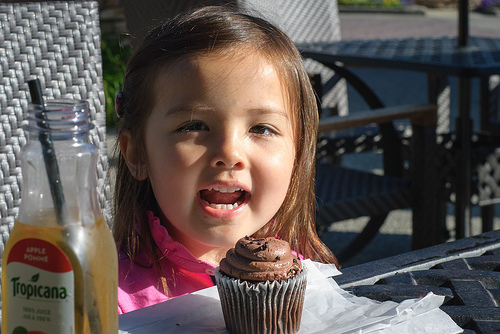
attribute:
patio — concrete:
[314, 12, 499, 265]